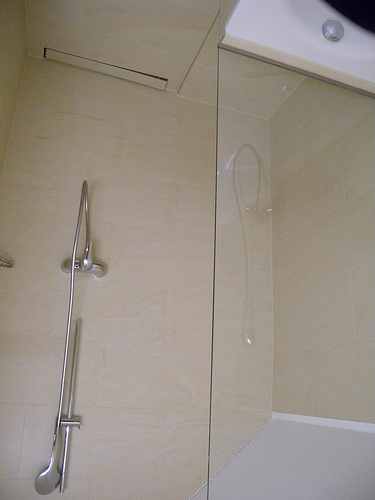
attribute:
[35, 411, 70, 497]
pipe — metallic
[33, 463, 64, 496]
shower head — silver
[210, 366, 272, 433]
glass — part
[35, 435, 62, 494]
shower head — Silver 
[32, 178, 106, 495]
hose — silver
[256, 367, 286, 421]
door — glass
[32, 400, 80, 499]
head — silver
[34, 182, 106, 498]
head — silver, shower head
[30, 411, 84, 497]
shower head — silver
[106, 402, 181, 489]
tiles — cream colored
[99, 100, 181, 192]
wall — tile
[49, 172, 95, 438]
hose — metal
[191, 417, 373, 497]
floor — white, part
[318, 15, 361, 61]
shower head — Silver 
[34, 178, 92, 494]
pipe — shiny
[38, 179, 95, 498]
hose — silver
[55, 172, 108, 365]
metal — part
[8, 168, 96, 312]
hose — metal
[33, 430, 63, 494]
shower head — silver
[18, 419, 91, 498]
shower head — Silver 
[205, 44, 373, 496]
glass — clear, part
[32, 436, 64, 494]
shower head — silver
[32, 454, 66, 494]
shower head — silver